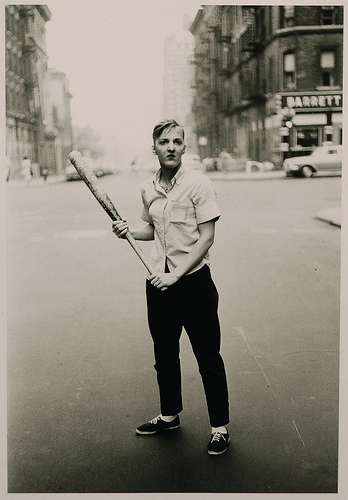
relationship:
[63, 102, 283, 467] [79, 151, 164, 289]
person holding bat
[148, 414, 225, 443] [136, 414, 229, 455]
shoe laces on shoes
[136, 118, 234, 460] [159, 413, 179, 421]
person wearing sock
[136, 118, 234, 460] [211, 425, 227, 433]
person wearing sock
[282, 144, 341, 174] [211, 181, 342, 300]
car on street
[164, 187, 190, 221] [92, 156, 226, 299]
pocket on shirt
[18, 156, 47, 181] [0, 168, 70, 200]
people walking on sidewalk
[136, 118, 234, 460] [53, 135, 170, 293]
person holding bat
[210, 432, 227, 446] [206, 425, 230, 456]
shoe laces on sneaker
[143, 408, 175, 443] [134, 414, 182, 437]
shoelace on sneaker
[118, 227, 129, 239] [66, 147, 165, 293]
finger wrapped around bat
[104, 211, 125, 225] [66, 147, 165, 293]
finger wrapped around bat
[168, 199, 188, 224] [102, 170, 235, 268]
pocket on shirt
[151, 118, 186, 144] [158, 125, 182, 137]
hair laying over forehead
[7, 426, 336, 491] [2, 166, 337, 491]
shadow on ground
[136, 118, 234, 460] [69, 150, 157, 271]
person holding baseball bat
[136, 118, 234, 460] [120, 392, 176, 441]
person wearing a sneaker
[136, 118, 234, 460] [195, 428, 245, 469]
person wearing a sneaker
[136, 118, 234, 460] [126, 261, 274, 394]
person wearing pants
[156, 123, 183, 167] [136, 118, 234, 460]
face of person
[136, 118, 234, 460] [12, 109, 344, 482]
person in street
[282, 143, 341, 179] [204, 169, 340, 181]
car in curb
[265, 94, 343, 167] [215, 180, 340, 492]
store across street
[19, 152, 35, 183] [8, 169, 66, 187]
woman on sidewalk